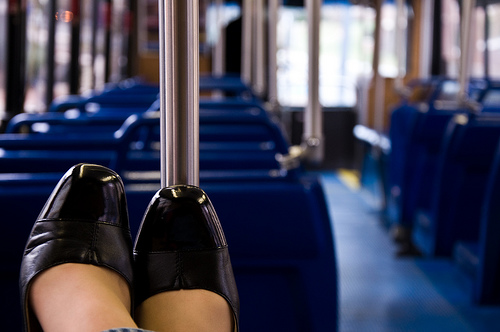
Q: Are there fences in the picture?
A: No, there are no fences.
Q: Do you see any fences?
A: No, there are no fences.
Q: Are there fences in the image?
A: No, there are no fences.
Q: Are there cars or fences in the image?
A: No, there are no fences or cars.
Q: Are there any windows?
A: Yes, there is a window.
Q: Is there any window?
A: Yes, there is a window.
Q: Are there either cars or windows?
A: Yes, there is a window.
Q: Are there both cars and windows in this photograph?
A: No, there is a window but no cars.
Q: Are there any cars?
A: No, there are no cars.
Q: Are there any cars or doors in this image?
A: No, there are no cars or doors.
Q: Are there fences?
A: No, there are no fences.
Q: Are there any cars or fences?
A: No, there are no fences or cars.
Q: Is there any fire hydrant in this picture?
A: No, there are no fire hydrants.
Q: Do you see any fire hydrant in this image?
A: No, there are no fire hydrants.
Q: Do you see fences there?
A: No, there are no fences.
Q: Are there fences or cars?
A: No, there are no fences or cars.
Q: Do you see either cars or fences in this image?
A: No, there are no fences or cars.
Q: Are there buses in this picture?
A: Yes, there is a bus.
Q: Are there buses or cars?
A: Yes, there is a bus.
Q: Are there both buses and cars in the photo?
A: No, there is a bus but no cars.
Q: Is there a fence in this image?
A: No, there are no fences.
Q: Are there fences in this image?
A: No, there are no fences.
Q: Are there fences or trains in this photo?
A: No, there are no fences or trains.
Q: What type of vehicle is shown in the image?
A: The vehicle is a bus.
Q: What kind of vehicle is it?
A: The vehicle is a bus.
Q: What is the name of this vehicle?
A: This is a bus.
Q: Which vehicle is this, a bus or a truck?
A: This is a bus.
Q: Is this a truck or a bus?
A: This is a bus.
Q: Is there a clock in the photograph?
A: No, there are no clocks.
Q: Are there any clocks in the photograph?
A: No, there are no clocks.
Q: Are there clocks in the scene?
A: No, there are no clocks.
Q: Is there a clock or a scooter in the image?
A: No, there are no clocks or scooters.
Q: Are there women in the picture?
A: Yes, there is a woman.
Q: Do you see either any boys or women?
A: Yes, there is a woman.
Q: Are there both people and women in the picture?
A: Yes, there are both a woman and a person.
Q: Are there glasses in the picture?
A: No, there are no glasses.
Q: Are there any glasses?
A: No, there are no glasses.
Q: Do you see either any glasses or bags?
A: No, there are no glasses or bags.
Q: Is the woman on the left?
A: Yes, the woman is on the left of the image.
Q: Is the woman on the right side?
A: No, the woman is on the left of the image.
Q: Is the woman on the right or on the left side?
A: The woman is on the left of the image.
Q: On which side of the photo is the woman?
A: The woman is on the left of the image.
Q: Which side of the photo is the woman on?
A: The woman is on the left of the image.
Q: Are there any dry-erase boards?
A: No, there are no dry-erase boards.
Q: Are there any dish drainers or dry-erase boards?
A: No, there are no dry-erase boards or dish drainers.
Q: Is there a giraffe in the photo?
A: No, there are no giraffes.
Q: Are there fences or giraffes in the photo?
A: No, there are no giraffes or fences.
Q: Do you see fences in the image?
A: No, there are no fences.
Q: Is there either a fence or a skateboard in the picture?
A: No, there are no fences or skateboards.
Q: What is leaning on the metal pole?
A: The shoe is leaning on the pole.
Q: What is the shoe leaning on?
A: The shoe is leaning on the pole.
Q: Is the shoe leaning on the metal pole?
A: Yes, the shoe is leaning on the pole.